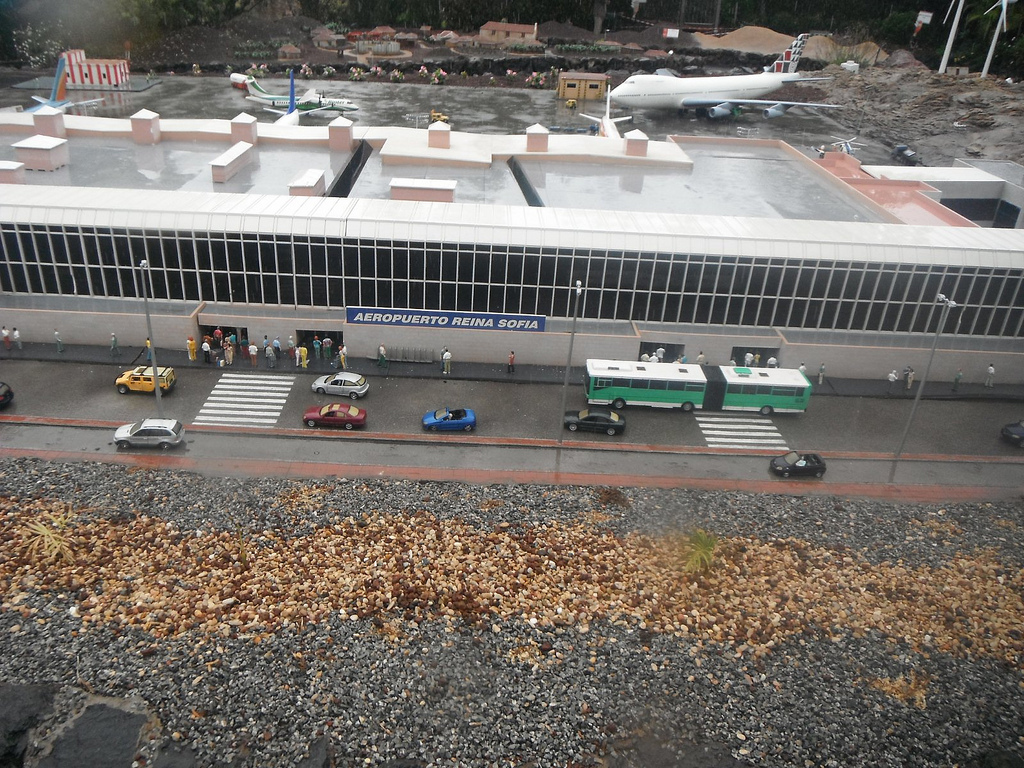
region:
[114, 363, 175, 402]
Yellow sports utility vehicle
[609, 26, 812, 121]
The large airplane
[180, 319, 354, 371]
The gathering of people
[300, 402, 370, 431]
The traveling red car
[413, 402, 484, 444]
Moving blue car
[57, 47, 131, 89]
Red and white striped building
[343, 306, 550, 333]
The sign on the building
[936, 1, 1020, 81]
White wind turbines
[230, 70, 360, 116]
Smaller airplane in the background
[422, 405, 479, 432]
the car is blue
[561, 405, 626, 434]
the car is black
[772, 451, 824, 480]
the car is black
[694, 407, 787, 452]
the lines are white and thick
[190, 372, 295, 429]
the lines are white and thick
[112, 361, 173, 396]
the humvee is yellow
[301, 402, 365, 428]
the car is red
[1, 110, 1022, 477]
the cars in front of the large building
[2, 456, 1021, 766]
the rocks are multi colored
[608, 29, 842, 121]
the airplane is parked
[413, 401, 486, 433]
blue car on street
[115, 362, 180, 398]
yellow automobile on street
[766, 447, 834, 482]
Car is black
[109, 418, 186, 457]
Car is silver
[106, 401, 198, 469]
Silver car on street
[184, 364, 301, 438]
White pedestrian cross walk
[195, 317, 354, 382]
People leaving building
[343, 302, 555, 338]
Blue and white sign on building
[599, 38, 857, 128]
An airplane at the airport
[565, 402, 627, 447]
A black car on the street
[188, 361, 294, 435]
A crosswalk on the street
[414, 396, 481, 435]
A blue car on the street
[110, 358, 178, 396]
A yellow truck on the street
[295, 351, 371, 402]
A silver car on the street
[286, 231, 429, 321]
Windows on a building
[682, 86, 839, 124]
A wing on a plane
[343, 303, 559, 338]
A sign on a building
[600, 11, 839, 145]
The white airplane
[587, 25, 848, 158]
A white airplane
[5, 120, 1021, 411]
the glass building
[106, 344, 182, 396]
The yellow truck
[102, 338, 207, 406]
A yellow truck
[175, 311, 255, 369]
The left entrance way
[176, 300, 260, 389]
A left entrance way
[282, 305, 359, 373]
The right entrance way of the airport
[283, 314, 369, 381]
A right entrance way of the airport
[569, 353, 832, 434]
a long green bus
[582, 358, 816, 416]
a green and white bus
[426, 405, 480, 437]
a small blue car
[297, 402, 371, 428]
a red car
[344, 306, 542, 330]
a blue sign on the building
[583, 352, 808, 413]
large green and white bus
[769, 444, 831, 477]
black sedan driving on the road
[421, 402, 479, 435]
blue sedan on the road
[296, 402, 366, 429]
red sedan on the road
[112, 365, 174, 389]
yellow Hummer on the road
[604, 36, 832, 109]
large white plane with red and green tail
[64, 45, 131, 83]
red and white striped building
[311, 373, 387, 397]
small silver car on road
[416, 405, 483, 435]
Blue car on road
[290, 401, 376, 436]
Red car on road